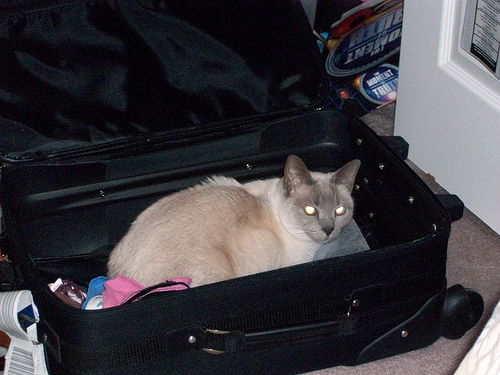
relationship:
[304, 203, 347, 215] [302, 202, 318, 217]
glare in right eye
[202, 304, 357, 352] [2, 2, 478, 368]
handle for a bag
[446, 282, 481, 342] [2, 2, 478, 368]
wheel for bag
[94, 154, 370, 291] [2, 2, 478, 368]
cat in a bag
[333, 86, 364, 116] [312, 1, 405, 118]
man on a box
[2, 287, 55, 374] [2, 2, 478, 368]
tag on bag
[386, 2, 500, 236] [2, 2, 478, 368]
door by bag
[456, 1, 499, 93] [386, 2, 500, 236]
window on door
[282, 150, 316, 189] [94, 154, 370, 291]
ear of cat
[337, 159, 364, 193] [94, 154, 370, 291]
ear of cat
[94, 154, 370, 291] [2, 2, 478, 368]
cat in bag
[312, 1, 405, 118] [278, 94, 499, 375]
box on floor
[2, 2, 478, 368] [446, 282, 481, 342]
bag has wheel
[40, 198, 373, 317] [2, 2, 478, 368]
clothing in bag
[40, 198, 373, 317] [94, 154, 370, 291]
clothing under cat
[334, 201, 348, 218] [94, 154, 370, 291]
left eye of cat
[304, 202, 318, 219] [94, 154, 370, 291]
right eye of cat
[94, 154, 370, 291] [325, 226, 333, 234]
cat has a nose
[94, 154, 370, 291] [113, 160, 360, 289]
cat has fur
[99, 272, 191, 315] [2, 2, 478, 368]
clothing are in bag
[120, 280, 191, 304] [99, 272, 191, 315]
lining on clothing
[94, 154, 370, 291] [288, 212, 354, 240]
cat has whiskers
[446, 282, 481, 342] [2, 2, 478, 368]
wheel on bag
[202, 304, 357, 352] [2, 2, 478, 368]
handle on bag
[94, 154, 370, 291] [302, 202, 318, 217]
cat has right eye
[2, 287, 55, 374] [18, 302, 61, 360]
tag on handle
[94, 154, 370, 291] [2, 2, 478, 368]
cat sitting in bag